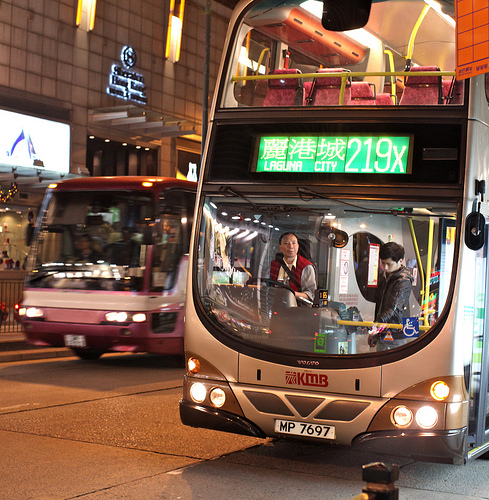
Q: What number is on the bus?
A: 219.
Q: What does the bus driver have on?
A: Seatbelt.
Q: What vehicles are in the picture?
A: Buses.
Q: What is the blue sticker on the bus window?
A: Handicap sign.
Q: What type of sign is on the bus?
A: Electric.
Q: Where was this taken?
A: A city street.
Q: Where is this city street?
A: Japan.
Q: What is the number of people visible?
A: Two.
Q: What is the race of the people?
A: Asian.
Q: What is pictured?
A: Two city passenger buses.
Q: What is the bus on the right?
A: A double decker bus.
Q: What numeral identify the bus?
A: MP 7697.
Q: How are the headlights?
A: Headlights are on.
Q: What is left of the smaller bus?
A: A building.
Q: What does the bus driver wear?
A: A red vest.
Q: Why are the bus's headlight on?
A: It's night.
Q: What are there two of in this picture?
A: Buses.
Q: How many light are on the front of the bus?
A: Six.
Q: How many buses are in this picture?
A: Two.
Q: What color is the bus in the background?
A: Pink.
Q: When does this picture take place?
A: Night time.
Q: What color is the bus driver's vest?
A: Red.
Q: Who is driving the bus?
A: A man.